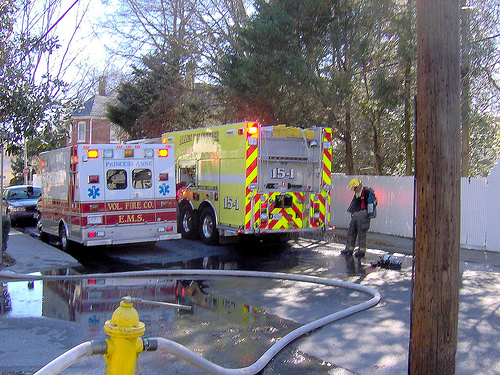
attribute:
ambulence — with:
[74, 171, 164, 252]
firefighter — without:
[338, 175, 381, 263]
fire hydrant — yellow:
[100, 298, 147, 371]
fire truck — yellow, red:
[170, 124, 332, 249]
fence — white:
[331, 172, 498, 254]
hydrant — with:
[100, 291, 150, 373]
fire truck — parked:
[167, 93, 345, 256]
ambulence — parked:
[38, 140, 185, 247]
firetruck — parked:
[169, 125, 329, 236]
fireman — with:
[329, 165, 376, 276]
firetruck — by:
[219, 118, 333, 245]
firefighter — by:
[341, 174, 375, 257]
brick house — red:
[78, 88, 139, 138]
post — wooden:
[408, 0, 461, 372]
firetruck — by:
[162, 117, 340, 247]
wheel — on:
[57, 220, 69, 252]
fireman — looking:
[337, 175, 381, 264]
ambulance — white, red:
[38, 143, 181, 253]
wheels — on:
[182, 203, 215, 234]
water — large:
[1, 249, 413, 374]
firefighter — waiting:
[334, 173, 377, 268]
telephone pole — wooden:
[405, 2, 454, 373]